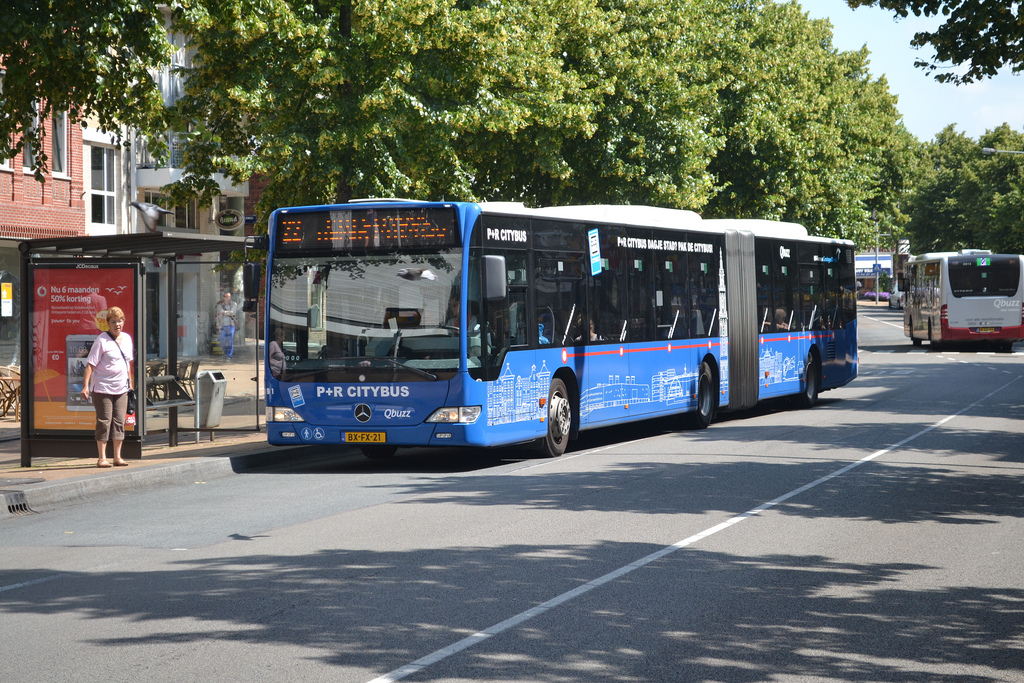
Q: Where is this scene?
A: On a city street.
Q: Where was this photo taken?
A: In the city.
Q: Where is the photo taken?
A: On the street.